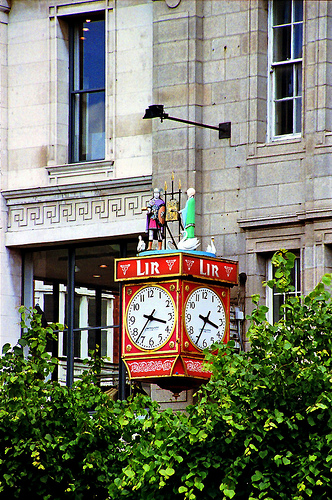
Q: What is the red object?
A: A clock.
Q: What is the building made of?
A: Stone.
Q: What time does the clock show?
A: 3:37.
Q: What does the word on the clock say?
A: Lir.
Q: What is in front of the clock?
A: Foliage.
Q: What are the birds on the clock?
A: Swans.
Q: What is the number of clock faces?
A: Two.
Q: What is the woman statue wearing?
A: A green dress.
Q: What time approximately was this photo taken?
A: 3:37 p.m.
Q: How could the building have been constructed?
A: With cinderblocks.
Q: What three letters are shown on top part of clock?
A: Lir.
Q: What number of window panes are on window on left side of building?
A: Two.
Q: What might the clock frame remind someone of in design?
A: Chinese art.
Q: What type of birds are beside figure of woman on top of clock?
A: Swans.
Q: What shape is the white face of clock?
A: Round.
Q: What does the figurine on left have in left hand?
A: Shield.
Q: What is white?
A: Clock's faces.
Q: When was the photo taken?
A: Daytime.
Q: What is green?
A: Trees.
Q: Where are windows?
A: On a building.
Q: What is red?
A: A clock.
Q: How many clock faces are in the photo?
A: Two.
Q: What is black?
A: Clock's hands.